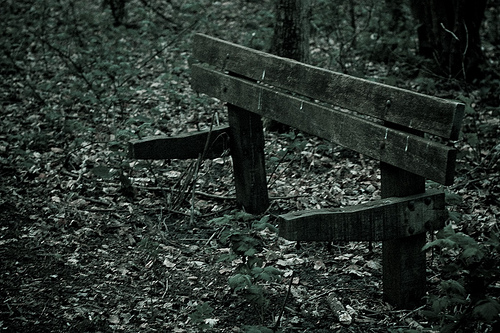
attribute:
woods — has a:
[8, 9, 495, 314]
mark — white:
[249, 58, 280, 84]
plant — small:
[419, 214, 499, 331]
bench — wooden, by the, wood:
[126, 32, 468, 300]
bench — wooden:
[278, 198, 440, 236]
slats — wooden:
[191, 30, 465, 140]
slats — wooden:
[183, 62, 456, 183]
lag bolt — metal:
[380, 93, 393, 110]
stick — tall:
[151, 107, 216, 220]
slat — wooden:
[189, 31, 465, 144]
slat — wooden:
[187, 61, 457, 186]